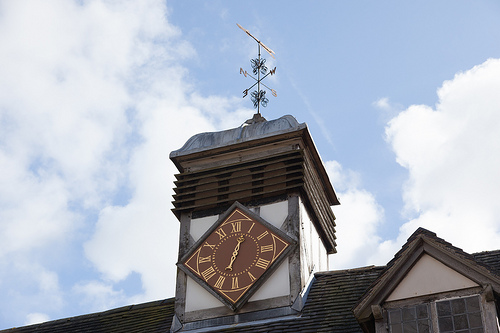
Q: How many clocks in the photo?
A: One.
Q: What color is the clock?
A: Brown and Gold.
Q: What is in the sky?
A: Clouds.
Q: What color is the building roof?
A: Brown.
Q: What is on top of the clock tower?
A: Weather vane.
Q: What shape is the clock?
A: Diamond.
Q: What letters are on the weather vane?
A: N,S, E, W.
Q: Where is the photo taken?
A: Near a clock tower.